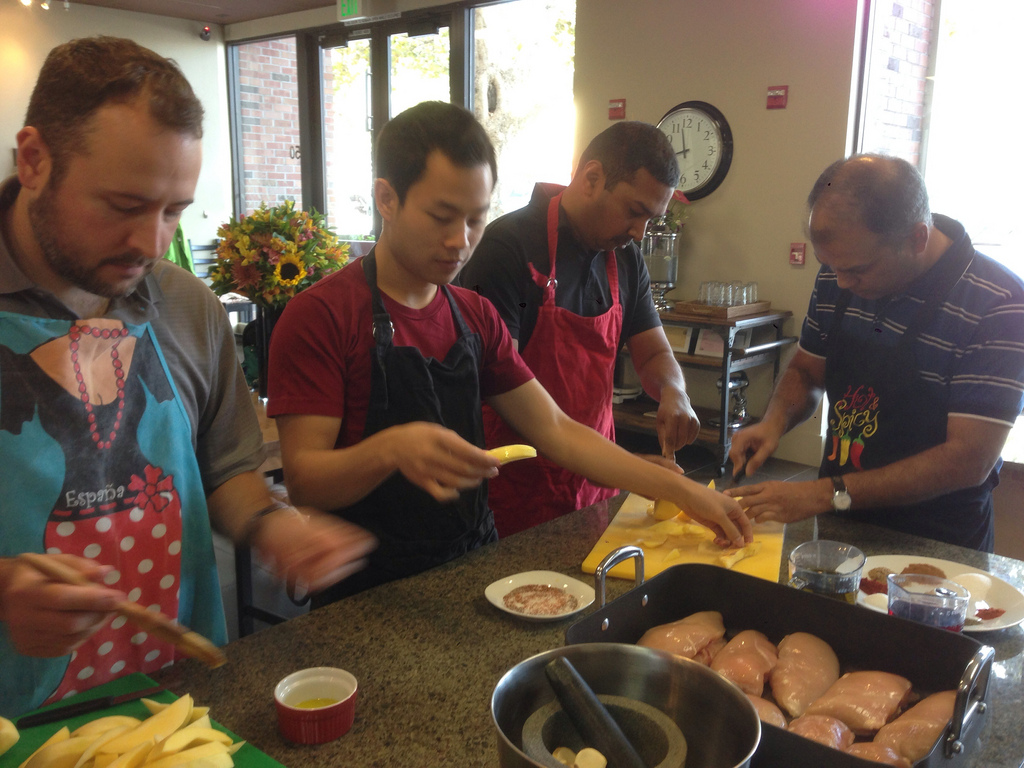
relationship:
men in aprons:
[29, 17, 993, 638] [15, 23, 992, 737]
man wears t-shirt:
[266, 79, 563, 563] [262, 257, 537, 551]